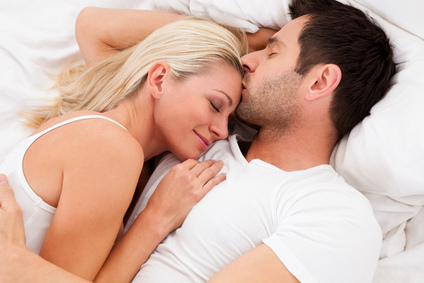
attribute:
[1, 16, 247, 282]
woman — laying down, smiling, lying in bed, content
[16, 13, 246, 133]
hair — blonde, blond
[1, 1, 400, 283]
man — lying down, kissing, lying in bed, laying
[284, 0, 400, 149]
hair — black, brown